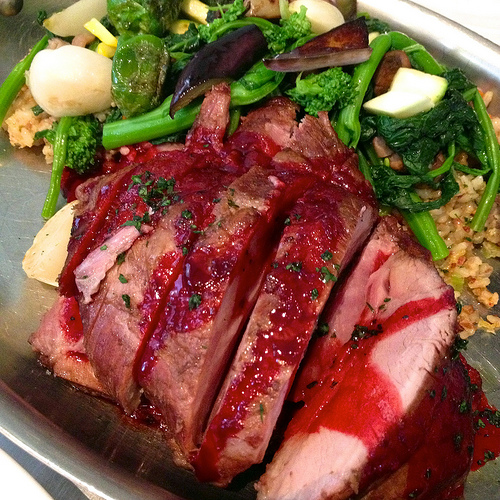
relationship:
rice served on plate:
[415, 90, 498, 340] [2, 0, 483, 499]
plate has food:
[2, 0, 483, 499] [42, 45, 438, 459]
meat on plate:
[27, 82, 479, 497] [2, 0, 483, 499]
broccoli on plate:
[248, 42, 355, 127] [2, 0, 483, 499]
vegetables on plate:
[1, 1, 485, 261] [2, 0, 483, 499]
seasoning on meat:
[98, 170, 498, 467] [23, 87, 461, 498]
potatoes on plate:
[33, 46, 120, 123] [2, 0, 483, 499]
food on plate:
[87, 79, 444, 386] [2, 0, 483, 499]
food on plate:
[0, 0, 500, 500] [2, 0, 483, 499]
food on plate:
[0, 0, 500, 500] [12, 58, 499, 358]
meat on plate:
[23, 87, 461, 498] [2, 0, 483, 499]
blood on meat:
[281, 158, 350, 429] [23, 87, 461, 498]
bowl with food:
[1, 1, 498, 496] [0, 0, 500, 500]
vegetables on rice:
[1, 1, 500, 260] [329, 85, 477, 270]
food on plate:
[0, 0, 500, 500] [13, 179, 48, 245]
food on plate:
[88, 57, 396, 307] [15, 167, 61, 232]